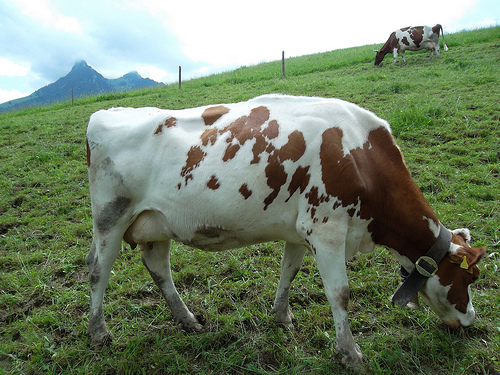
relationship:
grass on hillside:
[358, 50, 440, 117] [0, 20, 498, 371]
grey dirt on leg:
[96, 199, 128, 236] [82, 162, 143, 352]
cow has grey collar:
[77, 90, 493, 372] [386, 220, 456, 309]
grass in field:
[3, 24, 475, 370] [4, 29, 484, 370]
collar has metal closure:
[397, 235, 444, 303] [415, 252, 437, 277]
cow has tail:
[371, 24, 451, 67] [437, 21, 450, 52]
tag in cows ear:
[458, 255, 469, 269] [458, 245, 485, 269]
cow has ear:
[63, 92, 468, 349] [459, 242, 486, 269]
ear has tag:
[459, 242, 486, 269] [458, 255, 470, 272]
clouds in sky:
[6, 9, 161, 56] [203, 2, 355, 35]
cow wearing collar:
[77, 90, 493, 372] [390, 215, 452, 321]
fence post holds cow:
[175, 65, 184, 88] [371, 24, 451, 67]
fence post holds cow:
[175, 65, 184, 88] [77, 90, 493, 372]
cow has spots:
[77, 90, 493, 372] [158, 102, 350, 225]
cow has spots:
[372, 17, 455, 69] [401, 25, 430, 48]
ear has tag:
[452, 244, 486, 271] [458, 255, 469, 269]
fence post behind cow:
[279, 50, 289, 78] [368, 21, 448, 69]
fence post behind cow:
[177, 62, 185, 87] [368, 21, 448, 69]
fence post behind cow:
[68, 82, 78, 103] [368, 21, 448, 69]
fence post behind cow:
[279, 50, 289, 78] [77, 90, 493, 372]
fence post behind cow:
[177, 62, 185, 87] [77, 90, 493, 372]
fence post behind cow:
[68, 82, 78, 103] [77, 90, 493, 372]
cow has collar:
[77, 90, 493, 372] [413, 235, 440, 287]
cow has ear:
[77, 90, 493, 372] [451, 241, 487, 272]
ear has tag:
[451, 241, 487, 272] [460, 255, 470, 271]